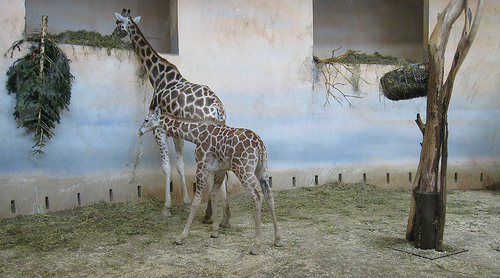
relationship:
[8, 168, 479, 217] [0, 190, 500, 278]
vertical lines are near the floor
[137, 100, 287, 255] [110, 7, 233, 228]
giraffe behind giraffe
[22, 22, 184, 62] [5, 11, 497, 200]
shelf inside of wall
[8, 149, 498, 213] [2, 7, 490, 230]
slits are inside of wall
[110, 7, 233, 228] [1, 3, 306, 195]
giraffe face wall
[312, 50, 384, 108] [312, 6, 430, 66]
straw on window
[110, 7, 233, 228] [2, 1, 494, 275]
giraffe in enclosure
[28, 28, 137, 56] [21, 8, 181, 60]
hay on shelf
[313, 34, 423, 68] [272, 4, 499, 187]
ledge on wall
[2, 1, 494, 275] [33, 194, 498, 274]
enclosure has floor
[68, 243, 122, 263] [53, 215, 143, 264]
hay on ground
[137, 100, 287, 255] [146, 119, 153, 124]
giraffe has eye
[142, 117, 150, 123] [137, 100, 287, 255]
eye belonging to giraffe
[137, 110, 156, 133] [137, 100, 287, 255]
face belonging to giraffe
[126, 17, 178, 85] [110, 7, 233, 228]
neck belonging to giraffe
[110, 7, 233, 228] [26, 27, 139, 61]
giraffe eating hay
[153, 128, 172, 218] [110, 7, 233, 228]
leg belonging to giraffe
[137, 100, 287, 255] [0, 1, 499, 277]
giraffe standing inside enclosure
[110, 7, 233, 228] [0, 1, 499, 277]
giraffe standing inside enclosure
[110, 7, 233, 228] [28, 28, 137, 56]
giraffe eating hay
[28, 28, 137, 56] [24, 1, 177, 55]
hay lying inside opening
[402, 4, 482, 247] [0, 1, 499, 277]
tree standing inside enclosure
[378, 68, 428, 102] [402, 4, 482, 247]
feeder hanging from tree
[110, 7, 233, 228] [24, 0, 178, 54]
giraffe feeding in hopper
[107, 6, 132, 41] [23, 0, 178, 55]
head stuck inside window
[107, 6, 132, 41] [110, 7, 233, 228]
head belonging to giraffe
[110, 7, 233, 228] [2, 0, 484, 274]
giraffe standing inside zoo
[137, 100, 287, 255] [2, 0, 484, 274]
giraffe standing inside zoo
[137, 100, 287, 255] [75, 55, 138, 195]
giraffe near wall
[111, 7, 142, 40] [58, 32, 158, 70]
head over ledge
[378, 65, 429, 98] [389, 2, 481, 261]
feeder in tree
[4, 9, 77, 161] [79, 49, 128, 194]
branch hanging on wall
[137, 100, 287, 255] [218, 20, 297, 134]
giraffe near wall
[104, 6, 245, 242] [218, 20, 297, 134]
giraffe near wall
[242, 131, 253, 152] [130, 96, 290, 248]
spot on giraffe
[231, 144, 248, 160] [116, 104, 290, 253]
spot on giraffe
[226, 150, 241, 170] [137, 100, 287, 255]
spot on giraffe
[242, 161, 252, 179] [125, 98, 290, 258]
spot on giraffe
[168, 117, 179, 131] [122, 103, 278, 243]
spot on giraffe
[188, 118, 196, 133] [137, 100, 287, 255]
spot on giraffe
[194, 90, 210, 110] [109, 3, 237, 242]
spot on giraffe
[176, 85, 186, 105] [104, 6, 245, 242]
spot on giraffe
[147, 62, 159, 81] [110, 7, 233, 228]
spot on giraffe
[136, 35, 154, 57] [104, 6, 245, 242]
spot on giraffe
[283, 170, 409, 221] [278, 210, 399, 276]
pile on ground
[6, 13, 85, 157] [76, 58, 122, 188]
tree upside down on wall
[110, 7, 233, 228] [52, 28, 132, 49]
giraffe eating hay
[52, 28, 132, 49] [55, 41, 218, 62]
hay on ledge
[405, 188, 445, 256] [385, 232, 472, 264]
wood bolted to plate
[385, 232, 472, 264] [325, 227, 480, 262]
plate on ground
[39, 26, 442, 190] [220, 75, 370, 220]
wall with paint